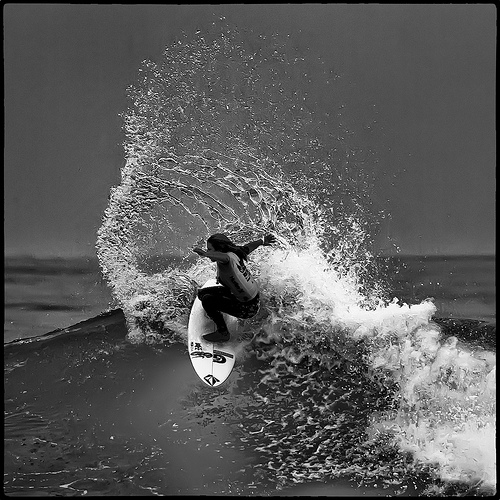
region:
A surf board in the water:
[188, 332, 232, 387]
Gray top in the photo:
[216, 251, 262, 301]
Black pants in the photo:
[196, 285, 259, 330]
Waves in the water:
[410, 346, 493, 474]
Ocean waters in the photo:
[97, 406, 212, 466]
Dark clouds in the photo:
[387, 93, 478, 195]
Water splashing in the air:
[105, 110, 343, 201]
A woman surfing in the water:
[190, 227, 280, 352]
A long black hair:
[203, 223, 249, 253]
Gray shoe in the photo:
[202, 330, 232, 343]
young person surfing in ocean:
[155, 213, 307, 393]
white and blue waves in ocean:
[25, 313, 150, 430]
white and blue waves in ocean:
[34, 269, 118, 337]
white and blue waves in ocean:
[72, 371, 162, 455]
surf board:
[185, 343, 242, 377]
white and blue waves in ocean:
[196, 382, 286, 452]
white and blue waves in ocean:
[275, 323, 337, 437]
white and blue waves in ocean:
[337, 253, 405, 380]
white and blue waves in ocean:
[421, 298, 466, 442]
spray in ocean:
[95, 116, 172, 218]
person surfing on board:
[164, 203, 266, 380]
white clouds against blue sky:
[12, 22, 87, 79]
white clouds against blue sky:
[28, 75, 76, 125]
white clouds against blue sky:
[18, 139, 75, 207]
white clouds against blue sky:
[84, 26, 164, 70]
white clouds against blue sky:
[218, 36, 302, 111]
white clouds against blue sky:
[295, 35, 439, 107]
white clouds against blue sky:
[390, 65, 451, 140]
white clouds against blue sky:
[274, 69, 355, 156]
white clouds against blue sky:
[351, 153, 475, 230]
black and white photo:
[3, 8, 497, 488]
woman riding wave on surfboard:
[3, 13, 492, 415]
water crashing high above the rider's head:
[4, 10, 482, 490]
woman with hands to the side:
[170, 208, 302, 439]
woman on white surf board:
[164, 203, 289, 407]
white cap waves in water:
[1, 195, 497, 492]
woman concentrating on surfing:
[112, 204, 311, 404]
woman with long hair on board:
[31, 213, 404, 438]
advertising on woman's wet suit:
[111, 199, 321, 411]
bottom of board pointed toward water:
[98, 187, 310, 416]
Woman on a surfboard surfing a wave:
[182, 230, 281, 393]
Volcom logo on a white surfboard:
[201, 371, 223, 387]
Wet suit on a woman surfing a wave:
[185, 246, 271, 346]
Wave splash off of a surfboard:
[92, 28, 380, 225]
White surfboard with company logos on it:
[184, 276, 236, 395]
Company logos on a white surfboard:
[187, 337, 235, 388]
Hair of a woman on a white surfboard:
[200, 232, 249, 262]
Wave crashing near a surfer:
[325, 310, 499, 475]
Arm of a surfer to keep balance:
[245, 232, 285, 250]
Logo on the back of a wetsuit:
[232, 258, 256, 288]